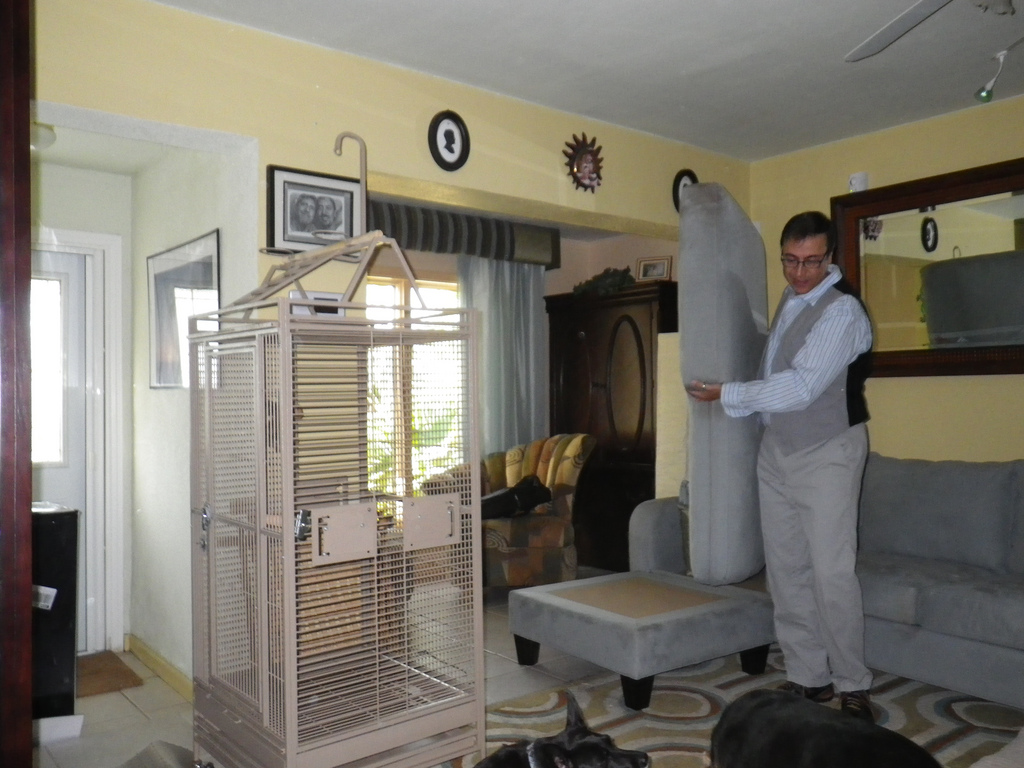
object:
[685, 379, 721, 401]
hand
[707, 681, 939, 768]
black dog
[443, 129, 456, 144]
head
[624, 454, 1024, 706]
grey couch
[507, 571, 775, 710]
grey ottoman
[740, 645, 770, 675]
black leg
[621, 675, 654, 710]
black leg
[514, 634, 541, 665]
black leg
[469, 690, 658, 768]
black dog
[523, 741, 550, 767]
collar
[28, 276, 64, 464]
window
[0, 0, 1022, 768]
building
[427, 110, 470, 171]
frame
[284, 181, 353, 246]
picture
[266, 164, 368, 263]
frame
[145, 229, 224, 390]
frame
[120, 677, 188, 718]
tile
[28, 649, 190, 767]
floor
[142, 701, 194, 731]
tile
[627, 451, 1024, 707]
sofa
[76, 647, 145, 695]
mat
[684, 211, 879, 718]
man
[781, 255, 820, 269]
glasses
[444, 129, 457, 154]
head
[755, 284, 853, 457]
grey vest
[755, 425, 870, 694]
pants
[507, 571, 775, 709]
footrest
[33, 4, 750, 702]
wall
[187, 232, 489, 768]
bird cage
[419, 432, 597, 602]
chair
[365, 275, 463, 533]
window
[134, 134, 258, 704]
wall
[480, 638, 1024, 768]
rug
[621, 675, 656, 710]
circle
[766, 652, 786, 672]
circle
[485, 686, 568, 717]
circle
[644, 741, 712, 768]
circle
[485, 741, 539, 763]
circle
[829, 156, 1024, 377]
mirror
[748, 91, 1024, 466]
wall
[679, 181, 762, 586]
cushion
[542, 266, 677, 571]
armoir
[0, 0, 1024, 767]
room